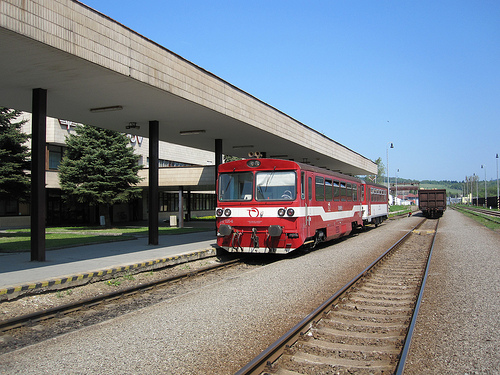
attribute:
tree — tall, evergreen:
[53, 119, 153, 233]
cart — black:
[349, 180, 495, 235]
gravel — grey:
[447, 267, 496, 354]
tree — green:
[33, 137, 210, 226]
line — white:
[313, 200, 346, 229]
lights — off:
[80, 87, 200, 152]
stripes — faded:
[80, 260, 101, 275]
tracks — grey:
[219, 313, 272, 345]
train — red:
[257, 196, 299, 234]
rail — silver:
[329, 270, 479, 366]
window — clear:
[229, 164, 307, 206]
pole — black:
[93, 134, 273, 251]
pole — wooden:
[33, 161, 54, 185]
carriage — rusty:
[398, 147, 467, 237]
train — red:
[157, 174, 318, 258]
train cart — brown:
[415, 185, 447, 218]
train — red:
[214, 158, 394, 265]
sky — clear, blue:
[87, 1, 484, 183]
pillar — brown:
[146, 148, 223, 254]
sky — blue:
[289, 19, 428, 133]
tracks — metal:
[295, 272, 385, 326]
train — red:
[204, 96, 310, 262]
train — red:
[231, 161, 315, 244]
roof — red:
[384, 170, 425, 207]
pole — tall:
[368, 114, 474, 304]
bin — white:
[153, 204, 190, 234]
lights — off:
[159, 145, 324, 267]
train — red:
[243, 155, 327, 240]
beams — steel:
[12, 99, 103, 284]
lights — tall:
[447, 147, 497, 215]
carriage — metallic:
[415, 186, 446, 216]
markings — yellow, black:
[2, 243, 218, 299]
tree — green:
[53, 120, 146, 225]